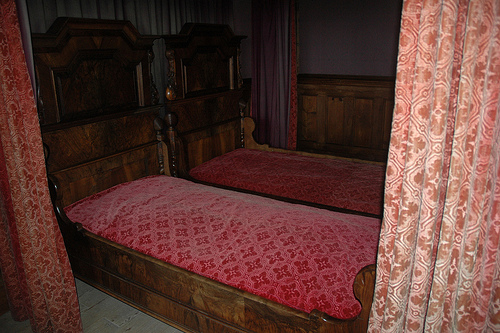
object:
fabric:
[0, 1, 83, 331]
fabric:
[367, 0, 500, 333]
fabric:
[62, 172, 380, 319]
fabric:
[191, 147, 387, 220]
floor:
[5, 274, 178, 332]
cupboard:
[296, 72, 394, 165]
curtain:
[0, 0, 83, 332]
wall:
[251, 7, 390, 155]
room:
[0, 0, 500, 332]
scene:
[0, 0, 499, 332]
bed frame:
[36, 18, 383, 332]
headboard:
[162, 12, 252, 175]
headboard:
[29, 16, 175, 207]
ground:
[0, 278, 189, 333]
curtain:
[366, 0, 499, 333]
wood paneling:
[183, 119, 238, 170]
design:
[400, 149, 460, 239]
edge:
[49, 194, 68, 254]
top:
[140, 195, 233, 236]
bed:
[0, 0, 500, 333]